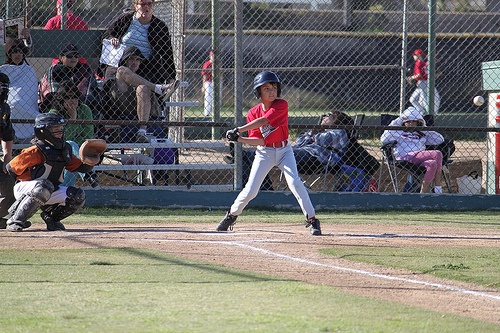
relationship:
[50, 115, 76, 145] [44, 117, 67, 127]
mask on face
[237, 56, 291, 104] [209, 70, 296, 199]
helmet on boy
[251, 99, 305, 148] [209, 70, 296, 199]
shirt on boy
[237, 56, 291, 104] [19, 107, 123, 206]
helmet on catcher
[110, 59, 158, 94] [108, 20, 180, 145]
leg of man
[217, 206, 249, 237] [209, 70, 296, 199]
shoe of boy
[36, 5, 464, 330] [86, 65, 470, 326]
game in action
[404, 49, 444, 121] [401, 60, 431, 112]
player wearing uniform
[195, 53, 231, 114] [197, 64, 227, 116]
player wearing uniform